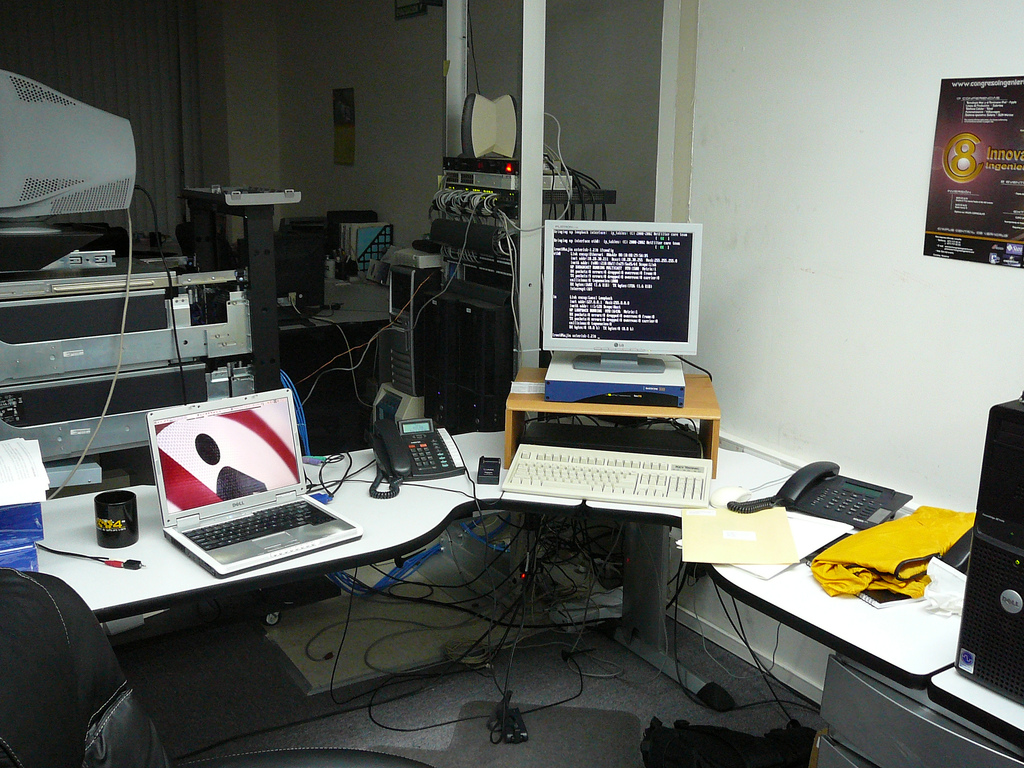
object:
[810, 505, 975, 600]
fabric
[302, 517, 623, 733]
cords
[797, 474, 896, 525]
features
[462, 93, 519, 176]
speakers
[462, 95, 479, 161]
facing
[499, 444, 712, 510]
keyboard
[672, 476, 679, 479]
pad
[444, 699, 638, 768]
protector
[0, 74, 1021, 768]
data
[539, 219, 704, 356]
monitor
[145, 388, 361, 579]
laptop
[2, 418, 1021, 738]
desk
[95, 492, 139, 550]
mug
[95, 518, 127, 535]
writing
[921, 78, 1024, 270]
flyer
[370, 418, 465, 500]
telephone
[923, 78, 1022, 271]
poster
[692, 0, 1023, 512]
wall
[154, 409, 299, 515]
design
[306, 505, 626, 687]
wires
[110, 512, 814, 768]
floor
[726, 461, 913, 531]
phone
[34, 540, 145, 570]
cord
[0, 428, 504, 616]
desk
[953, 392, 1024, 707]
computer tower